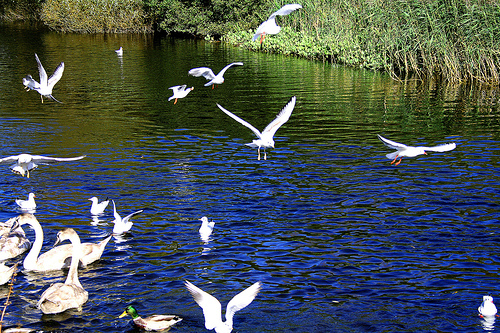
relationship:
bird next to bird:
[20, 52, 65, 102] [1, 150, 86, 177]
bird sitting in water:
[37, 227, 93, 320] [279, 175, 387, 245]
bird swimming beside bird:
[20, 52, 67, 104] [115, 305, 182, 332]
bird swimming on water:
[82, 187, 112, 220] [6, 19, 496, 330]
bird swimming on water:
[193, 211, 217, 251] [6, 19, 496, 330]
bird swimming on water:
[472, 288, 497, 324] [6, 19, 496, 330]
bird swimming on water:
[112, 297, 192, 329] [6, 19, 496, 330]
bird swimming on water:
[31, 222, 89, 319] [6, 19, 496, 330]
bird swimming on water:
[20, 52, 67, 104] [6, 19, 496, 330]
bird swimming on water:
[110, 40, 129, 60] [6, 19, 496, 330]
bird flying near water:
[211, 90, 300, 168] [6, 19, 496, 330]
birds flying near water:
[371, 131, 461, 169] [6, 19, 496, 330]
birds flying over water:
[184, 1, 461, 174] [6, 19, 496, 330]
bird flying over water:
[20, 52, 67, 104] [6, 19, 496, 330]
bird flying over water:
[161, 79, 199, 111] [6, 19, 496, 330]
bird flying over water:
[3, 146, 91, 186] [6, 19, 496, 330]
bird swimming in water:
[20, 52, 67, 104] [6, 19, 496, 330]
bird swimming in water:
[86, 196, 109, 217] [6, 19, 496, 330]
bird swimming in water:
[103, 196, 148, 245] [6, 19, 496, 330]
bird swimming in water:
[474, 294, 500, 320] [6, 19, 496, 330]